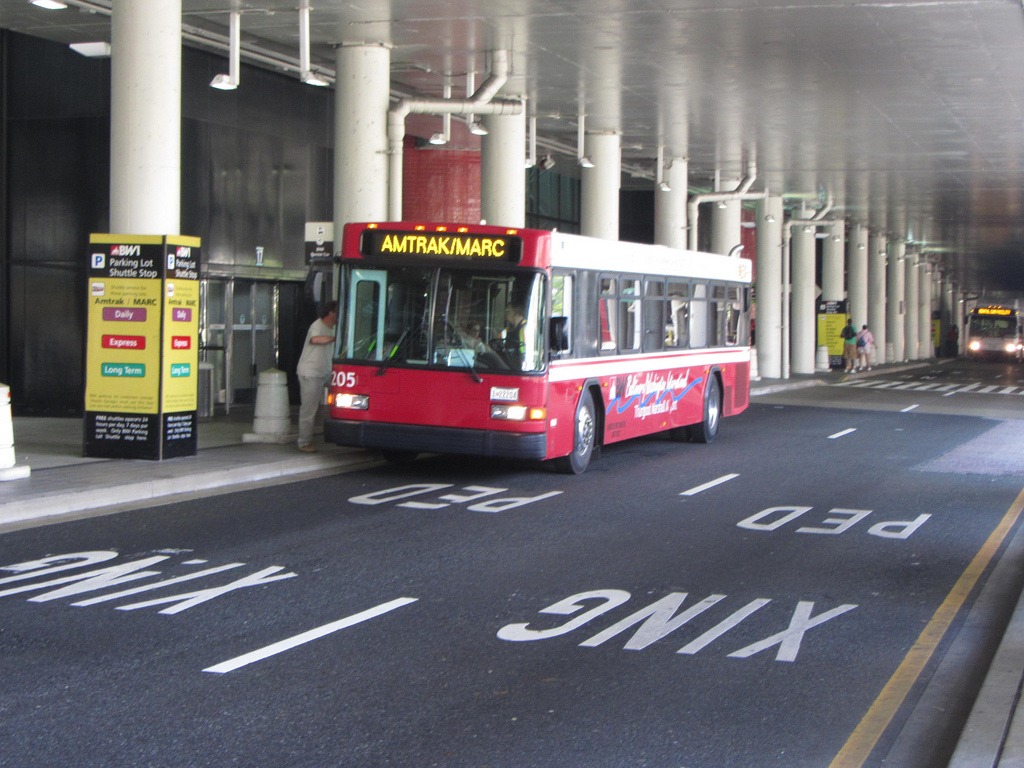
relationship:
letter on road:
[582, 588, 725, 664] [9, 357, 1014, 759]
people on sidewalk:
[835, 312, 881, 379] [0, 346, 940, 528]